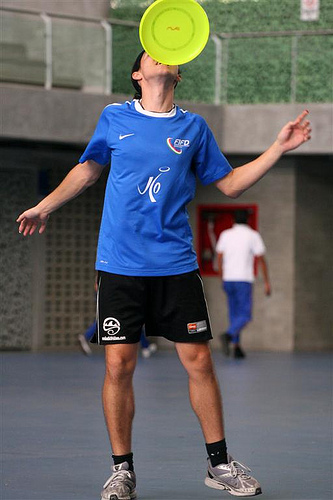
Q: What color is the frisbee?
A: Yellow.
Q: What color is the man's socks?
A: Black.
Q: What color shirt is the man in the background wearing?
A: White.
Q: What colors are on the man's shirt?
A: Blue & White.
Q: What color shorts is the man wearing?
A: Black.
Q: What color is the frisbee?
A: Yellow.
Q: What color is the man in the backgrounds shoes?
A: Black.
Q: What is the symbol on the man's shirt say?
A: FIFD.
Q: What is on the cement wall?
A: A Fence.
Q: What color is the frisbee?
A: Yellow.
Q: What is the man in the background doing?
A: Walking.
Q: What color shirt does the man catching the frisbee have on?
A: Blue.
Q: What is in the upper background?
A: A green hedgerow.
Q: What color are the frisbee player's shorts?
A: Black.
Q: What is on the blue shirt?
A: A white logo.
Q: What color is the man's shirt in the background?
A: White.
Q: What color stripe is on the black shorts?
A: White.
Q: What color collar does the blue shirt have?
A: White.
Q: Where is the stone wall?
A: Behind the chain link fence.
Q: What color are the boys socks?
A: Black.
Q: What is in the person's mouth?
A: A frisbee.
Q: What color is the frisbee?
A: Yellow.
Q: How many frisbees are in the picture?
A: One.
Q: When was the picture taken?
A: Daytime.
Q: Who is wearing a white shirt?
A: Man in background.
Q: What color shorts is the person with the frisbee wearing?
A: Black.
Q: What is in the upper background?
A: Hedges.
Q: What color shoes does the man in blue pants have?
A: Black.